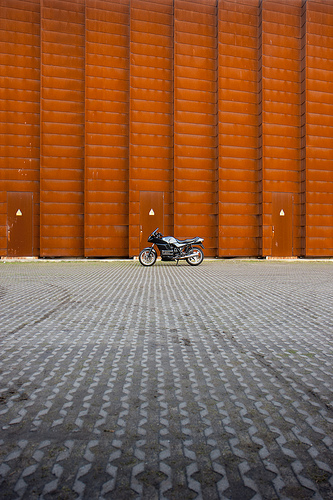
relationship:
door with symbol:
[271, 193, 292, 257] [278, 209, 284, 215]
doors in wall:
[3, 178, 301, 251] [62, 179, 259, 269]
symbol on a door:
[269, 207, 293, 222] [119, 180, 174, 247]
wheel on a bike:
[137, 246, 156, 267] [139, 225, 204, 265]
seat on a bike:
[176, 236, 199, 244] [119, 204, 212, 277]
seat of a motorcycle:
[176, 237, 197, 243] [138, 229, 205, 266]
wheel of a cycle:
[139, 248, 157, 266] [125, 224, 200, 273]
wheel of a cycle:
[186, 242, 212, 266] [120, 211, 208, 271]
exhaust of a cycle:
[174, 252, 201, 260] [129, 225, 214, 267]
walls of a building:
[171, 60, 251, 140] [0, 0, 332, 258]